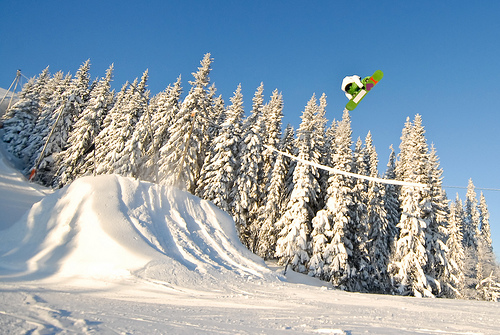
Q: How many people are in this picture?
A: One.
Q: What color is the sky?
A: Blue.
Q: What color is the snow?
A: White.